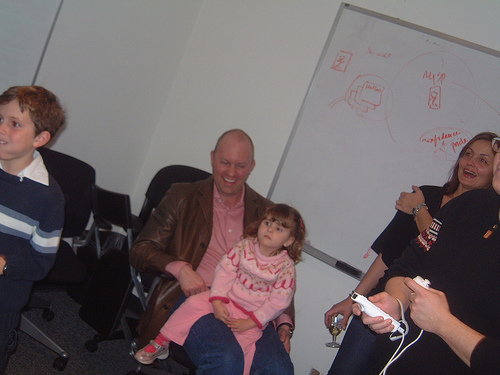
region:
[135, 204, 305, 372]
A girl is sitting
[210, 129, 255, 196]
The man is smiling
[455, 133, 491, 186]
A woman is smiling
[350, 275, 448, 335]
Man holding Wii remote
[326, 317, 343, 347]
A glass of wine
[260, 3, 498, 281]
White board on wall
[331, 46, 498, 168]
Red writing on board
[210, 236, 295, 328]
The sweater is pink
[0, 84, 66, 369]
A boy is standing around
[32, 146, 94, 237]
Chair back is black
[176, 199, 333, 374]
red headed little girl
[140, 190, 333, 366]
little girl wearing all pink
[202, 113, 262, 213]
balding man laughing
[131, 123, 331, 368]
little girl sitting on her dad's lap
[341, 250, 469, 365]
WII controllers in two hands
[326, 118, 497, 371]
lady watching a man play WII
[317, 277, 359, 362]
a half full glass of wine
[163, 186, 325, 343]
girl watching someone play the WII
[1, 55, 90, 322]
little boy playing WII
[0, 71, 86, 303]
little boy with mouth full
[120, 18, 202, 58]
this is the wall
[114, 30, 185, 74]
the wall is white in color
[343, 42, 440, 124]
the wall has drawings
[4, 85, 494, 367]
these are some people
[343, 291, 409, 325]
this is a remote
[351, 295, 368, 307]
the remote is white in color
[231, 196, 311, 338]
this is a girl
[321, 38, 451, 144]
the writings are in red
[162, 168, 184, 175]
this is a chair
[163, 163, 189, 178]
the chair is black in color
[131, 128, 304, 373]
man holding little girl on his lap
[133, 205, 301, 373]
young child wearing a pink outfit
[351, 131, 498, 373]
person playing a wii game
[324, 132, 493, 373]
woman observing game in the back of the room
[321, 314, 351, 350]
appears to be an alcoholic beverage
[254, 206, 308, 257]
little girl is the only person not smiling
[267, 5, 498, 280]
white board on the wall has writing on it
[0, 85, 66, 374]
young boy is in the corner of picture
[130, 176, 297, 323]
wearing a brown leather jacket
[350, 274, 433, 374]
wii controllers in hand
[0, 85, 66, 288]
A boy in a white and blue shirt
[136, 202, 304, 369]
A small child with red hair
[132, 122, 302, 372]
A man with a child on his lap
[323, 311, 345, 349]
A small wine glass in a woman's hand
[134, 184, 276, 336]
A red brown leather jacket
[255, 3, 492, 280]
A dry erase board on the wall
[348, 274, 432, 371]
A wii mote and nunchuck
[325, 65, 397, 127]
Drawings on a board in red writing.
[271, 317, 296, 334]
A small wristwatch on a man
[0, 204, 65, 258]
A white and blue stripe on a shirt